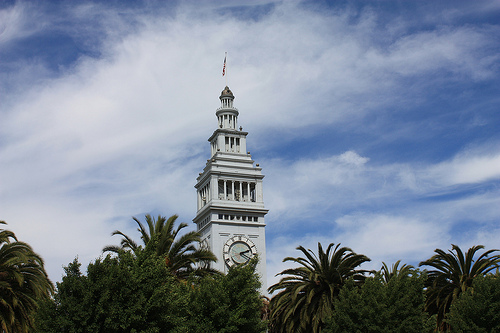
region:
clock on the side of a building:
[222, 231, 262, 276]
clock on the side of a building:
[222, 230, 268, 270]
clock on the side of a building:
[216, 223, 266, 277]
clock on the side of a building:
[216, 227, 267, 283]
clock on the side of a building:
[222, 235, 265, 276]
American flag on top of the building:
[216, 48, 237, 85]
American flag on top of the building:
[220, 51, 230, 89]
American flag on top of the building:
[217, 44, 232, 82]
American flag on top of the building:
[218, 48, 230, 83]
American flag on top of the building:
[216, 47, 229, 87]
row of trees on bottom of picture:
[0, 217, 497, 332]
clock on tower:
[221, 233, 258, 271]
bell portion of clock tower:
[195, 164, 265, 227]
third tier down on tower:
[205, 129, 249, 156]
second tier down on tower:
[214, 105, 239, 128]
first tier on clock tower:
[218, 82, 235, 107]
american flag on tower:
[219, 49, 232, 86]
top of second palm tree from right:
[102, 208, 224, 289]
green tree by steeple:
[0, 227, 51, 331]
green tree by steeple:
[151, 267, 263, 331]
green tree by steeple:
[105, 215, 216, 267]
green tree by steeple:
[265, 240, 369, 331]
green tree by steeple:
[427, 236, 498, 295]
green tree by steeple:
[347, 270, 434, 330]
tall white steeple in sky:
[200, 90, 267, 299]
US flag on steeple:
[220, 52, 227, 81]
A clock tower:
[180, 19, 297, 302]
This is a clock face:
[197, 215, 282, 280]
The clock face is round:
[208, 218, 270, 290]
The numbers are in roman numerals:
[215, 228, 265, 275]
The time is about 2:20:
[213, 233, 268, 272]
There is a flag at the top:
[215, 35, 241, 86]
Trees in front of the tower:
[6, 220, 481, 329]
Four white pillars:
[220, 178, 255, 203]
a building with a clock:
[207, 201, 267, 276]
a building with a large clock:
[208, 215, 270, 310]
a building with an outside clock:
[217, 221, 283, 311]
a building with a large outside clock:
[222, 228, 277, 300]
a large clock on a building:
[187, 198, 257, 303]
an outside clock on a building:
[201, 211, 256, 283]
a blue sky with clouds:
[304, 50, 486, 278]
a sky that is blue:
[264, 66, 461, 249]